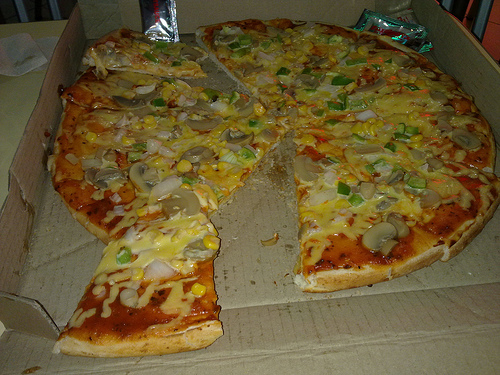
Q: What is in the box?
A: Pizza.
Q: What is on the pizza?
A: Cheese.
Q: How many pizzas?
A: 1.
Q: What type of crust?
A: Thin.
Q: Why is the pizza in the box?
A: To eat.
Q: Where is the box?
A: A table.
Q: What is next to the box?
A: Reciept.